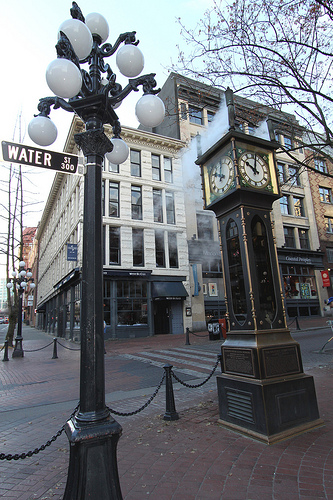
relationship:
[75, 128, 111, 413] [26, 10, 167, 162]
post below light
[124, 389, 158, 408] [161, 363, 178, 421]
chain on post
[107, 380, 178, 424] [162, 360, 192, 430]
metal chain and pole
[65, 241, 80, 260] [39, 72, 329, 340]
flag on building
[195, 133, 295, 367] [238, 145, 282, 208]
clock tower with clock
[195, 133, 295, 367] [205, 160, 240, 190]
clock tower with clock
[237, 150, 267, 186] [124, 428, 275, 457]
clock sitting on sidewalk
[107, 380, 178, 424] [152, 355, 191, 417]
metal chain attached to poles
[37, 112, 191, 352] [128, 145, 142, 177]
building with window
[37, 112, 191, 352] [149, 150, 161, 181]
building with window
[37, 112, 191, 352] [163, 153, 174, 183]
building with window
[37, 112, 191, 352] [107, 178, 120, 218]
building with window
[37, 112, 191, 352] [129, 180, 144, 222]
building with window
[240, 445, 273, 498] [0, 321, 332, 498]
lines on ground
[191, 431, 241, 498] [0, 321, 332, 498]
lines on ground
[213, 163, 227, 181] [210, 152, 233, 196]
hands on clock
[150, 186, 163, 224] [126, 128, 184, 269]
window on building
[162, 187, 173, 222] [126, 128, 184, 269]
window on building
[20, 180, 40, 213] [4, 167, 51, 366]
branches on tree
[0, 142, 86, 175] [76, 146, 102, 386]
sign attached to a pole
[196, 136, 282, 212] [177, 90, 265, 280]
clock has steam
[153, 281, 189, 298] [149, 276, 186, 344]
awning over doorway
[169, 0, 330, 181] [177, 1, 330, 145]
branches hanging over tree